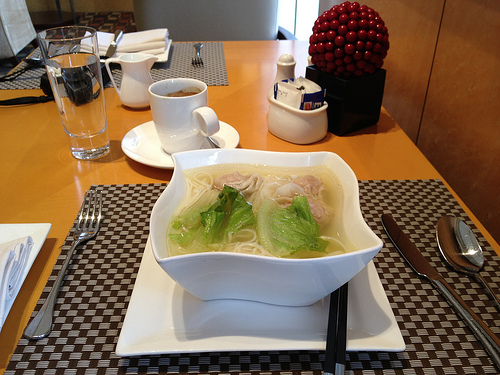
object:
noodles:
[218, 230, 264, 255]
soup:
[169, 162, 356, 258]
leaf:
[259, 195, 327, 255]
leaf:
[172, 181, 256, 246]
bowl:
[151, 148, 380, 307]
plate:
[114, 288, 407, 357]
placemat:
[7, 183, 162, 375]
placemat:
[172, 42, 228, 85]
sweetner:
[274, 77, 326, 109]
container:
[269, 98, 328, 146]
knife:
[105, 29, 126, 58]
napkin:
[121, 28, 171, 60]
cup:
[150, 77, 220, 153]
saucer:
[122, 121, 175, 175]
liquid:
[46, 50, 107, 137]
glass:
[35, 26, 111, 162]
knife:
[380, 208, 499, 367]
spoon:
[435, 213, 500, 325]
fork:
[24, 191, 104, 340]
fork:
[192, 41, 204, 67]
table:
[0, 87, 123, 224]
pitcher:
[107, 51, 158, 110]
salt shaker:
[274, 55, 296, 87]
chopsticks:
[326, 283, 350, 374]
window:
[277, 1, 319, 41]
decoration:
[306, 1, 390, 134]